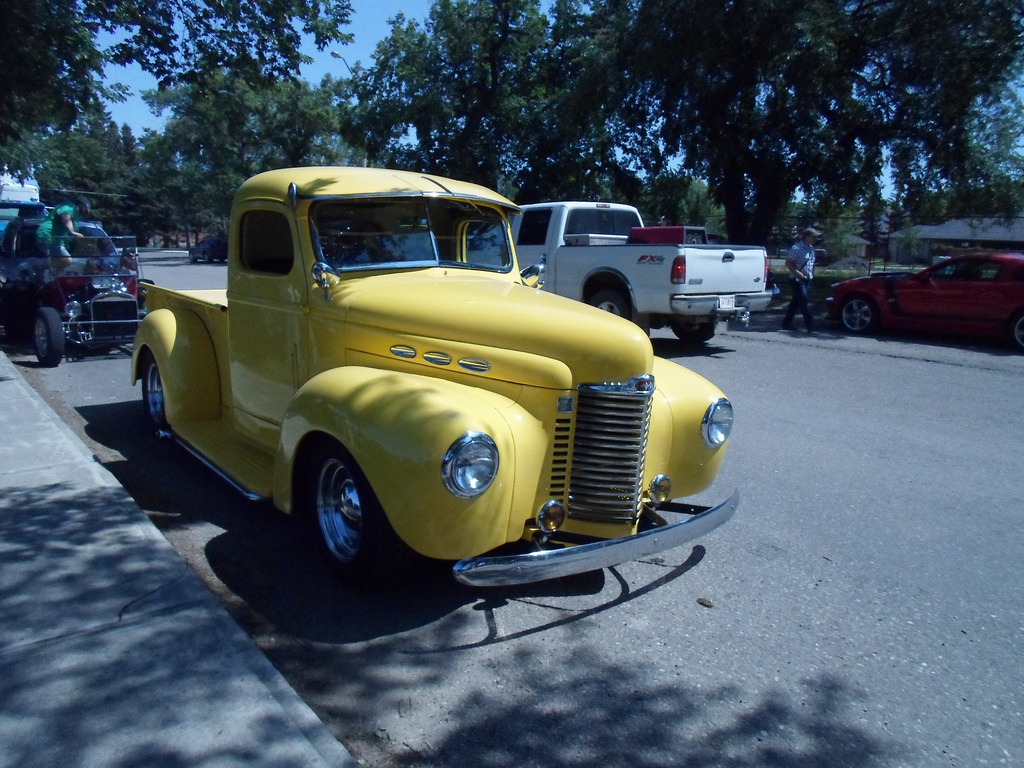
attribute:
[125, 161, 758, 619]
truck — old, vintage, bright, yellow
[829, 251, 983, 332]
side — of a red car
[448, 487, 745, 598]
vehicle bumper — shiny, metal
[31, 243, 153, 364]
front end — of antique convertible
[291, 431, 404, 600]
tire — with shiny hubcap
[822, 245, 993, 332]
side — of red sports car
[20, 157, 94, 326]
person — dressed, green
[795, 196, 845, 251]
cap — blue, baseball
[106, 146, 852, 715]
truck — modern, white, pickup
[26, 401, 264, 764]
sidewalk — grey, paved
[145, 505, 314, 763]
curb — grey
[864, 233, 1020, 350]
car — red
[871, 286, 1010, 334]
stripe — black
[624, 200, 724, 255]
dog cage — red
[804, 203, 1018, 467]
mustang — red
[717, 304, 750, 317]
tag — white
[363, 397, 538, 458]
truck — yellow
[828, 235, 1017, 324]
mustang — red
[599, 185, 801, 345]
truck — white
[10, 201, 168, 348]
car — classic, maroon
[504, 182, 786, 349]
truck — white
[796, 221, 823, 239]
cap — baseball cap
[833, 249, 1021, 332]
car — red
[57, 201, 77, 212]
hat — green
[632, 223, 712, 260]
object — red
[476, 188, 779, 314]
truck — white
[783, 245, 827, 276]
shirt — blue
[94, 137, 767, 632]
truck — yellow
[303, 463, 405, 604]
tire — black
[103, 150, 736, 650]
truck — yellow